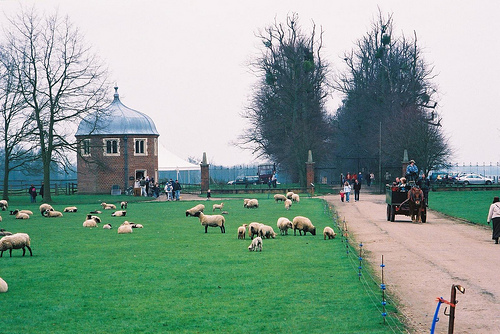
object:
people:
[134, 175, 182, 201]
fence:
[328, 202, 465, 332]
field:
[0, 193, 405, 332]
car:
[449, 174, 494, 186]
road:
[435, 185, 499, 189]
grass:
[2, 196, 400, 331]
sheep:
[12, 209, 29, 219]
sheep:
[293, 215, 316, 236]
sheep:
[82, 217, 98, 228]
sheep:
[39, 203, 54, 216]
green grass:
[11, 231, 345, 330]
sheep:
[0, 232, 33, 258]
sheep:
[248, 237, 262, 252]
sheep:
[324, 226, 337, 240]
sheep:
[118, 220, 133, 233]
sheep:
[194, 211, 226, 233]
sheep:
[277, 217, 293, 236]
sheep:
[243, 198, 259, 209]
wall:
[84, 158, 120, 185]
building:
[75, 80, 163, 194]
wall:
[135, 156, 156, 168]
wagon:
[386, 182, 429, 225]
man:
[406, 159, 420, 181]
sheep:
[0, 189, 338, 254]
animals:
[1, 189, 341, 263]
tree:
[227, 8, 334, 184]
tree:
[321, 4, 454, 188]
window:
[80, 139, 90, 156]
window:
[103, 139, 118, 154]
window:
[135, 140, 145, 154]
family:
[339, 179, 362, 203]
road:
[317, 181, 484, 331]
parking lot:
[419, 164, 483, 185]